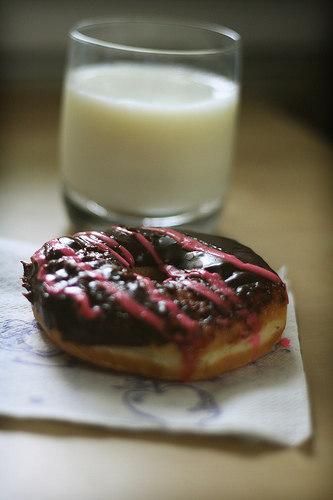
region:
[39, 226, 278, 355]
Stripes of pink frosting on the donut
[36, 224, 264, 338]
Chocolate glaze covering the donut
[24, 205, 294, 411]
A delicious looking chocolate donut on the napkin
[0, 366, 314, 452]
A white napkin beneath the donut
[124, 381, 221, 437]
A blue apple design on the white napkin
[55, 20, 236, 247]
A small glass of milk by the donut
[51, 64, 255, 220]
White milk in the short glass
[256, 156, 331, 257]
A wooden table beneath the donut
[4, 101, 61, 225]
The table is made of wood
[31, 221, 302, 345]
The donut has no sprinkles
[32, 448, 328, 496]
The table is made of wood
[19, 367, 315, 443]
The napkin on the table is white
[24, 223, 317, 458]
The doughnut sitting on the napkin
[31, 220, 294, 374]
The doughnut has chocolate sauce on it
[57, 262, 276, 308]
The pink icing on the doughnut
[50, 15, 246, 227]
A glass of milk on the table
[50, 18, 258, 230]
The glass on the table is round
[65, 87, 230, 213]
The milk on the glass is white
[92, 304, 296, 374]
The side of the doughnut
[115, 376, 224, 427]
The apple design on the napkin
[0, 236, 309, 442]
A paper napkin under a donut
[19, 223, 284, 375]
A donut on a napkin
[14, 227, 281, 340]
some chocolate glaze on the donut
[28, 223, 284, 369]
some pink frosting on the donut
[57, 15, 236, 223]
A small drinking glass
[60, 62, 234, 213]
Some milk in a glass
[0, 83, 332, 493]
A table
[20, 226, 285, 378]
A chocolate glazed donut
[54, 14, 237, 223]
A glass with milk in it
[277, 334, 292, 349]
some icing on the napkin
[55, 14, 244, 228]
glass of milk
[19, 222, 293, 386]
chocolate glazed doughnut on a napkin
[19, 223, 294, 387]
a delicious looking doughnut on a napkin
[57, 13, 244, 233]
a frosty glass of cold milk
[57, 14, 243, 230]
a clear glass holding good tasting milk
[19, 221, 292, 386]
A sweet but fattening glazed doughnut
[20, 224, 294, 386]
temptingly moist glazed doughnut on the table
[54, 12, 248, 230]
a glass of cold milk waiting to be drank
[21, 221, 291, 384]
a pink striped chocolate glazed doughnut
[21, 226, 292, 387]
A devilishly delicious chocolate glazed doughnut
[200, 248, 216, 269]
light reflecting on the icing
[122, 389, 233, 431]
blue floral pattern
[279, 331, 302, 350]
pink crumbs on the napkin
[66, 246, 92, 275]
sweet pink icing stripe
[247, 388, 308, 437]
corner of a white napkin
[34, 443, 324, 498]
white wooden table top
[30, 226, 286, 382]
a chocolate doughnut with pink stripes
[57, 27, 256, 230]
a glass of milk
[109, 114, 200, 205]
rich white milk in a glass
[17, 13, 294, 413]
a delicious snack on the table